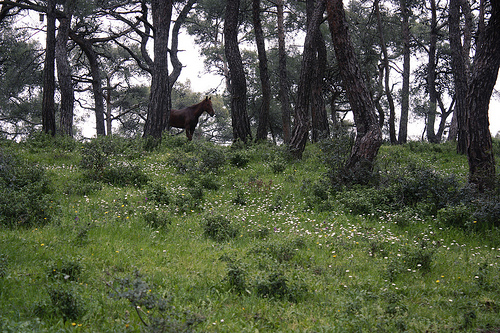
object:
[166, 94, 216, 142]
horse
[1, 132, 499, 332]
grass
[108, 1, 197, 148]
tree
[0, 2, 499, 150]
sky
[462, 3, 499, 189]
trunk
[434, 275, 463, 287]
flowers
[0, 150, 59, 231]
bush